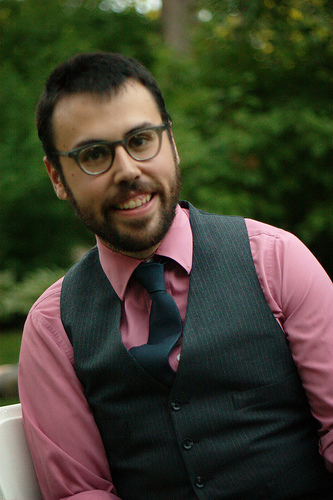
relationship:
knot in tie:
[123, 263, 179, 292] [126, 257, 185, 390]